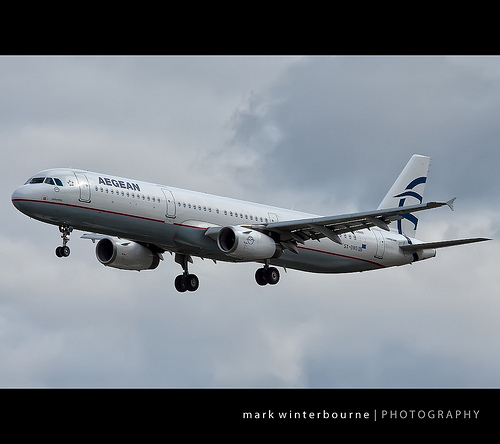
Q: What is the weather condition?
A: Cloudy.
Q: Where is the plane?
A: In the sky.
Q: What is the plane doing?
A: Flying.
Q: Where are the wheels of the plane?
A: Underneath the plane.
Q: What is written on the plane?
A: Aegean.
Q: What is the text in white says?
A: Mark winterbourne photography.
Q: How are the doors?
A: Closed.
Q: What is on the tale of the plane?
A: A logo.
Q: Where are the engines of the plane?
A: On both sides of the plane.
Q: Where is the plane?
A: In the air.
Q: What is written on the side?
A: Aegean.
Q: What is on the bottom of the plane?
A: Wheels.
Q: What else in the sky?
A: Clouds.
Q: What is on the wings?
A: Engines.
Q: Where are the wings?
A: On the sides.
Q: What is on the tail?
A: The company logo.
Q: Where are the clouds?
A: All over the sky.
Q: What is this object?
A: A plane.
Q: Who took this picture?
A: Mark Winterbourne.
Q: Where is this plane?
A: The sky.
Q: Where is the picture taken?
A: The sky.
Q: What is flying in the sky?
A: A plane.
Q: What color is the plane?
A: White.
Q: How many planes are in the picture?
A: One.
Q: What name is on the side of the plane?
A: AEGEAN.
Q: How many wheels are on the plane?
A: 6.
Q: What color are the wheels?
A: Black.